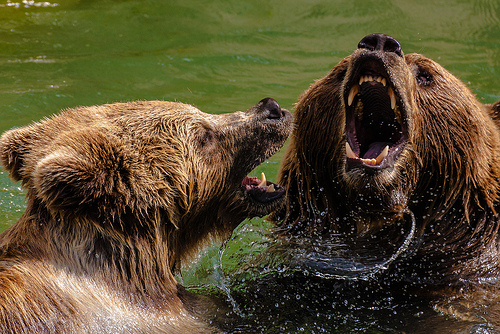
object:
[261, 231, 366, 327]
water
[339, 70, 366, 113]
bear's teeth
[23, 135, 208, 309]
bear's fur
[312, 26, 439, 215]
bear's mouth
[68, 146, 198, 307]
bear's fur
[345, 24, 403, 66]
bear's nose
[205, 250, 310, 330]
water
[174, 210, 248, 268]
bear's fur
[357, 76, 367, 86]
tooth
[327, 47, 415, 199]
mouth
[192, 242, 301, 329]
water droplets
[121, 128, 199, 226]
fur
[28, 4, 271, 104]
river water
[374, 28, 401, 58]
nostrils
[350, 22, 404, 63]
nose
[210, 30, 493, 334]
bear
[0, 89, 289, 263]
head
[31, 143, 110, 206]
ear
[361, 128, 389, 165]
tongue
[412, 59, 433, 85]
eye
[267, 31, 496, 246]
head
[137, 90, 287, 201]
face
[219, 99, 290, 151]
snout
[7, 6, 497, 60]
water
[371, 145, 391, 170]
teeth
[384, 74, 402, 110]
teeth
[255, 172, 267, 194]
teeth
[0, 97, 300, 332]
bear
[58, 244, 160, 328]
fur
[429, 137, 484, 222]
fur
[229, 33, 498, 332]
bear